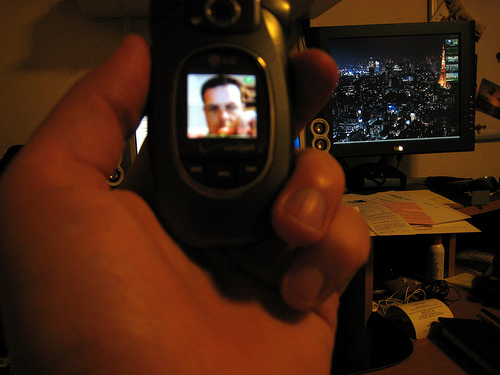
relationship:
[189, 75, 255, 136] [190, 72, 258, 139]
part of picture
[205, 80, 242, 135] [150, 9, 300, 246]
face on phone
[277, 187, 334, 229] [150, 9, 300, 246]
fingernail on phone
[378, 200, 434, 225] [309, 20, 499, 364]
paper in background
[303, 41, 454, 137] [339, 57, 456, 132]
picture of city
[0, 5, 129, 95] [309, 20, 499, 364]
wall in background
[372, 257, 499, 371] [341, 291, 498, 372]
stuff on floor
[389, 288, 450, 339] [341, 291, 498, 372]
paper on floor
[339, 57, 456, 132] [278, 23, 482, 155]
city lights on tv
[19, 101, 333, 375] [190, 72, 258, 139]
person taking selfie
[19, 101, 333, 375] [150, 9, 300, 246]
person holding cellphone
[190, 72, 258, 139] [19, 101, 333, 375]
picture of person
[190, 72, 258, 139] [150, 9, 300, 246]
picture in cellphone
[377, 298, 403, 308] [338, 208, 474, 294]
cord under table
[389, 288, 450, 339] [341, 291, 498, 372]
book on floor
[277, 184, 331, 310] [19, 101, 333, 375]
fingernails on person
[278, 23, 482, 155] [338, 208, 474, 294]
television sitting on stand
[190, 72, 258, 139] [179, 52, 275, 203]
picture of cell phone screen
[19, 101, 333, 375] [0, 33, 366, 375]
person has hand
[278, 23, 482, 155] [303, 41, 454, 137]
photo of citscape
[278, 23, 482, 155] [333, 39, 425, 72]
photo at night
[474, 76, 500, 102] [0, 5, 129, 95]
postcard on wall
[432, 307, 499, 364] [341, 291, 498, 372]
book on floor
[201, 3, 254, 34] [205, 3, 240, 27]
camera has camera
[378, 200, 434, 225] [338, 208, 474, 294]
paper on top of table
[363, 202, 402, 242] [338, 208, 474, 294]
receipt on top of table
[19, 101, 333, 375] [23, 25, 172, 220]
person has thumb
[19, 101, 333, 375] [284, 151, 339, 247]
person has finger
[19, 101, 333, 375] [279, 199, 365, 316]
person has finger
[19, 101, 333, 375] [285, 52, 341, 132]
person has finger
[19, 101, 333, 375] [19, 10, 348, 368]
person has hand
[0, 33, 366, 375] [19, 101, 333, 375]
hand hand of a person